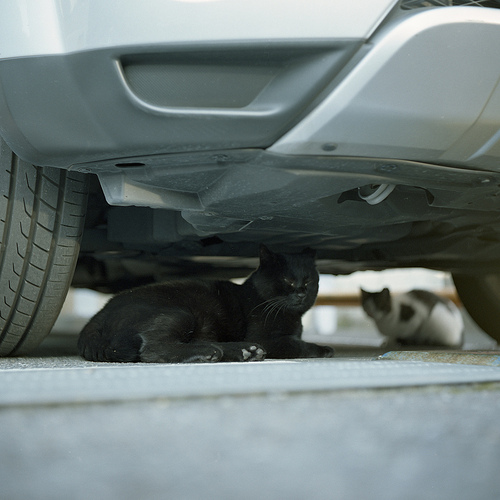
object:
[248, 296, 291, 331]
whiskers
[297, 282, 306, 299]
nose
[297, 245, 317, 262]
ear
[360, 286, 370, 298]
ear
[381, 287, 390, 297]
ear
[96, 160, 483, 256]
undercarriage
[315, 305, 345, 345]
bucket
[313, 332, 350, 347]
ground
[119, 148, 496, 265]
bottom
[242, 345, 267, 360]
paw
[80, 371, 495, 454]
parking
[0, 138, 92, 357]
tread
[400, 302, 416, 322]
spots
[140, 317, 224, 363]
legs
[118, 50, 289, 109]
light gray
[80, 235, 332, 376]
tiles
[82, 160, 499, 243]
underside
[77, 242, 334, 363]
cats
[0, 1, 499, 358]
car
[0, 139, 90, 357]
tire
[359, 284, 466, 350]
black white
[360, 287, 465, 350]
cat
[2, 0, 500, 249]
car bumper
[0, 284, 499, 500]
pavement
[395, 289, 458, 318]
cat's back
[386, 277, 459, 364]
back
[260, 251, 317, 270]
hair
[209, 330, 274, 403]
bottom pad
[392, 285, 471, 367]
back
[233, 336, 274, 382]
bottom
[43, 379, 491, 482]
part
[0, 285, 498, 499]
parking lot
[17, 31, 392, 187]
bottom part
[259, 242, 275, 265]
ears